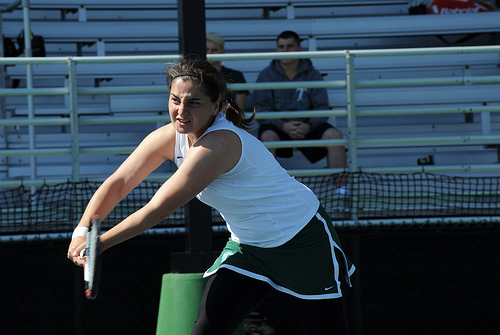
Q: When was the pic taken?
A: During the day.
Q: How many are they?
A: 1.